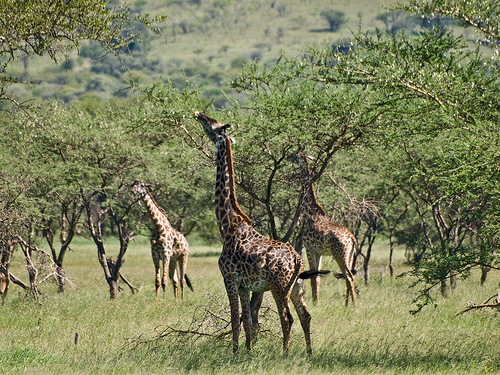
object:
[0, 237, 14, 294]
trunk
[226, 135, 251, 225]
mane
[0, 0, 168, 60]
leaves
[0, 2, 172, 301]
tree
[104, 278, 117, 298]
trunk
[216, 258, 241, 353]
leg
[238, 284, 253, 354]
leg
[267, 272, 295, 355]
leg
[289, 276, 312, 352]
leg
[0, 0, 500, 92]
hill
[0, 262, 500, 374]
grass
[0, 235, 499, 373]
field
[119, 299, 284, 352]
fallen branches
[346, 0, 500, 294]
trees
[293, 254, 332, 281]
giraffe tail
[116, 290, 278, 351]
branch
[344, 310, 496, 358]
ground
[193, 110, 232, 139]
giraffe head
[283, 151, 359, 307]
giraffe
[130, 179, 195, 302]
giraffe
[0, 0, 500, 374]
photo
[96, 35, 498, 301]
tree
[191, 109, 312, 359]
giraffe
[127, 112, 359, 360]
giraffes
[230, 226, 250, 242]
spot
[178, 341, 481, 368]
shadow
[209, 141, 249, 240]
neck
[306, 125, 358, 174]
limbs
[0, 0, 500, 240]
grove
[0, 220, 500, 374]
pasture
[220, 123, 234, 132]
ossicones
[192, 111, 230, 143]
head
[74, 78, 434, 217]
detail